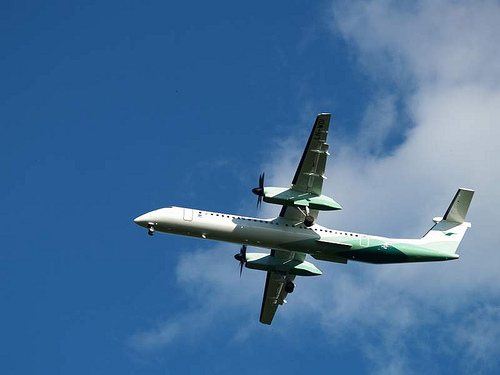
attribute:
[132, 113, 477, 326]
airplane — white, green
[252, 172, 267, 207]
propeller — black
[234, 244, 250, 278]
propeller — black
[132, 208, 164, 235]
nose — pointed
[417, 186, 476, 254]
tail — green, white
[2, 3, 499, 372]
sky — blue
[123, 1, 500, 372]
clouds — white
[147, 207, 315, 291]
landing gear — down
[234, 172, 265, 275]
propellers — black